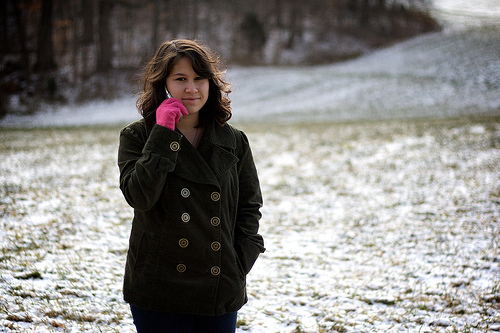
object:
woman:
[118, 39, 267, 333]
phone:
[163, 85, 183, 123]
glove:
[156, 98, 188, 131]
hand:
[156, 97, 188, 131]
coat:
[118, 109, 267, 316]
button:
[181, 188, 190, 198]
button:
[181, 212, 191, 223]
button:
[178, 238, 189, 248]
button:
[177, 263, 187, 273]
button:
[210, 191, 221, 201]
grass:
[0, 0, 499, 333]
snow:
[1, 0, 500, 332]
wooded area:
[0, 0, 443, 121]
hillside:
[0, 0, 499, 127]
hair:
[130, 37, 237, 129]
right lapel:
[162, 151, 195, 187]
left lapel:
[196, 137, 239, 177]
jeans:
[130, 303, 238, 332]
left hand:
[236, 250, 258, 269]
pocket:
[233, 237, 260, 273]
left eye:
[194, 76, 204, 81]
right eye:
[176, 77, 188, 82]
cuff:
[144, 123, 183, 163]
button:
[170, 140, 180, 151]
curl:
[136, 90, 155, 115]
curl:
[218, 104, 232, 125]